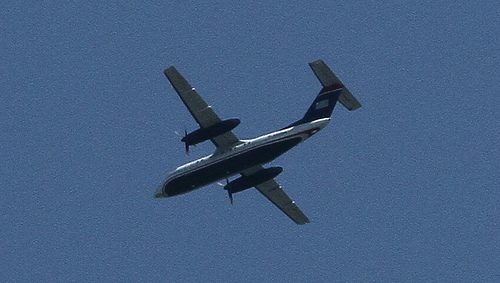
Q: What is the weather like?
A: It is clear.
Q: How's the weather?
A: It is clear.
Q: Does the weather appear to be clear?
A: Yes, it is clear.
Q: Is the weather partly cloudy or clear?
A: It is clear.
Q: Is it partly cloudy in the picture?
A: No, it is clear.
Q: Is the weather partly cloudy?
A: No, it is clear.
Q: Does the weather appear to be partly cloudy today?
A: No, it is clear.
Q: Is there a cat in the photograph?
A: No, there are no cats.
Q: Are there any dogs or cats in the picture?
A: No, there are no cats or dogs.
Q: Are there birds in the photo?
A: No, there are no birds.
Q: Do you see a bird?
A: No, there are no birds.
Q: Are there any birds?
A: No, there are no birds.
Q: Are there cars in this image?
A: No, there are no cars.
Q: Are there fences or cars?
A: No, there are no cars or fences.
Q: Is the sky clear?
A: Yes, the sky is clear.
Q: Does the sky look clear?
A: Yes, the sky is clear.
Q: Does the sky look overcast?
A: No, the sky is clear.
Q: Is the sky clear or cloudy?
A: The sky is clear.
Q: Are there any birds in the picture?
A: No, there are no birds.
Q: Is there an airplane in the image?
A: Yes, there is an airplane.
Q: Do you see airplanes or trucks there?
A: Yes, there is an airplane.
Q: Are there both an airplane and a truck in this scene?
A: No, there is an airplane but no trucks.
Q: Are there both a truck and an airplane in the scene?
A: No, there is an airplane but no trucks.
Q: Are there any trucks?
A: No, there are no trucks.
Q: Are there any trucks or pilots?
A: No, there are no trucks or pilots.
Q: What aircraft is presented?
A: The aircraft is an airplane.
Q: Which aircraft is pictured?
A: The aircraft is an airplane.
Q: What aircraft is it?
A: The aircraft is an airplane.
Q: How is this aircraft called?
A: This is an airplane.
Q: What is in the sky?
A: The plane is in the sky.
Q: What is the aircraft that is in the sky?
A: The aircraft is an airplane.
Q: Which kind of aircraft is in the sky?
A: The aircraft is an airplane.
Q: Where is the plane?
A: The plane is in the sky.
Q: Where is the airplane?
A: The plane is in the sky.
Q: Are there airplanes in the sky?
A: Yes, there is an airplane in the sky.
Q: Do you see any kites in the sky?
A: No, there is an airplane in the sky.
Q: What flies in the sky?
A: The airplane flies in the sky.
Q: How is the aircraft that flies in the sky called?
A: The aircraft is an airplane.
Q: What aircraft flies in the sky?
A: The aircraft is an airplane.